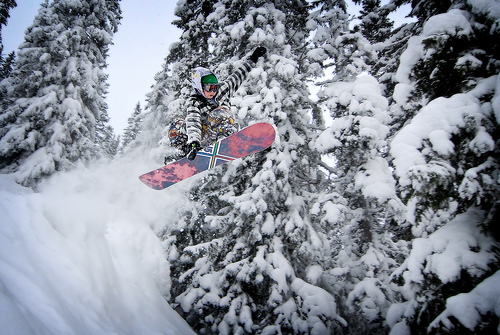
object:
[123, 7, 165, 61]
sky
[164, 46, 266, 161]
person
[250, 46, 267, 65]
mittens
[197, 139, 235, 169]
colorful x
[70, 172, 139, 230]
plume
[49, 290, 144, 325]
snow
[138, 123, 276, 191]
snowboard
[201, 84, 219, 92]
goggles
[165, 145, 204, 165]
feet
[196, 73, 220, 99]
head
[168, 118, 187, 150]
leg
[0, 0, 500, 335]
snow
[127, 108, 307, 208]
jump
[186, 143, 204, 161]
hand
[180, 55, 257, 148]
black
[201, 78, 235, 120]
ski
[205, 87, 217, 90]
eyes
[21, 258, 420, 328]
snow